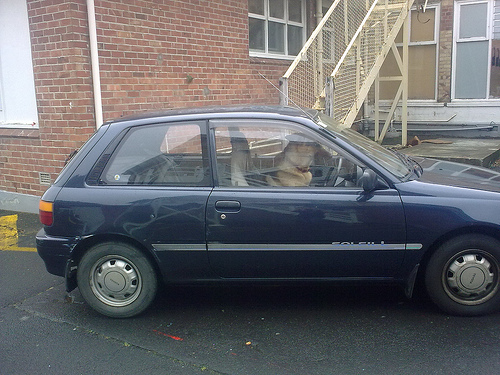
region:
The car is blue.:
[75, 115, 479, 267]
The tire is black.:
[73, 237, 164, 315]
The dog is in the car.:
[261, 132, 319, 217]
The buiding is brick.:
[120, 9, 210, 85]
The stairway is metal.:
[293, 9, 403, 142]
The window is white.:
[243, 4, 322, 56]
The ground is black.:
[170, 312, 336, 372]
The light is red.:
[33, 191, 72, 241]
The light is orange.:
[27, 192, 55, 233]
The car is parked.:
[48, 96, 476, 313]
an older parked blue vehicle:
[27, 95, 499, 319]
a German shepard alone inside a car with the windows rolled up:
[246, 124, 346, 206]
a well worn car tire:
[60, 227, 187, 324]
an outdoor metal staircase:
[259, 5, 439, 155]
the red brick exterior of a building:
[106, 13, 245, 100]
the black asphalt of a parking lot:
[184, 308, 424, 369]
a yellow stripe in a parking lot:
[1, 210, 38, 275]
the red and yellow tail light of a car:
[38, 193, 70, 233]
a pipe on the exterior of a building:
[73, 1, 115, 127]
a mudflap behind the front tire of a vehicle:
[396, 258, 425, 310]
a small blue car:
[34, 105, 497, 317]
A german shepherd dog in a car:
[264, 132, 331, 186]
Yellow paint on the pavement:
[1, 214, 35, 252]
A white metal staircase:
[280, 0, 407, 145]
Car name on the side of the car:
[330, 238, 384, 246]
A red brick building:
[2, 0, 497, 213]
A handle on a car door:
[212, 200, 244, 213]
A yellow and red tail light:
[37, 200, 51, 225]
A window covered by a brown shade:
[376, 5, 438, 100]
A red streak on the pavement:
[154, 327, 181, 341]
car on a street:
[10, 58, 467, 370]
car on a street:
[181, 117, 452, 354]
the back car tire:
[52, 216, 177, 350]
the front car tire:
[390, 218, 498, 325]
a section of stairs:
[262, 0, 437, 153]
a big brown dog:
[253, 120, 329, 206]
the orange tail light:
[33, 190, 70, 236]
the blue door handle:
[206, 197, 266, 232]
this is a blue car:
[29, 94, 498, 328]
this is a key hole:
[213, 210, 232, 224]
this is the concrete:
[0, 104, 493, 373]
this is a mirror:
[355, 157, 387, 196]